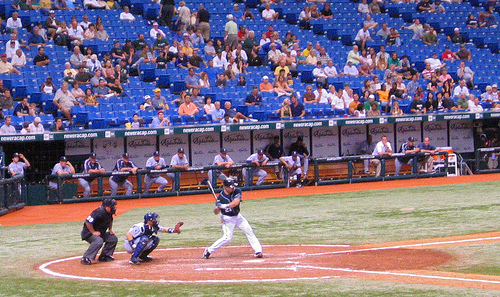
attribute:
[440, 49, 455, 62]
shirt — red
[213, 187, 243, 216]
shirt — blue, black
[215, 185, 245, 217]
shirt — blue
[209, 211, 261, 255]
pants — white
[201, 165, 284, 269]
baseball player — wearing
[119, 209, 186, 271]
baseball player — squatting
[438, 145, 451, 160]
orange cooler — white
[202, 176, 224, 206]
bat — long, baseball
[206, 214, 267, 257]
legs — apart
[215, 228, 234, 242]
knee — bent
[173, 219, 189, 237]
glove — catcher's, brown, player's, white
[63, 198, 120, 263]
umpire — squatting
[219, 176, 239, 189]
helmet — black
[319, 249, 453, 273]
pitch — brown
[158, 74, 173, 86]
seat — blue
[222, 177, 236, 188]
helmet — dark, baseball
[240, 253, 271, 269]
base — flat, white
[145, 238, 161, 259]
leg pad — protective